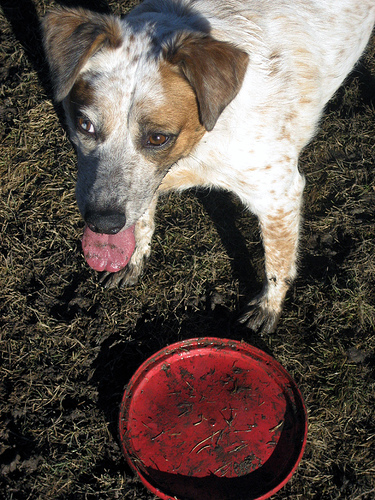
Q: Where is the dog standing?
A: In the mud.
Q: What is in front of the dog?
A: A frisbee.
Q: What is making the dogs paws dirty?
A: Mud.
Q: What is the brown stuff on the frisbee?
A: Mud.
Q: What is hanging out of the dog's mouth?
A: Tongue.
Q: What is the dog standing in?
A: Mud.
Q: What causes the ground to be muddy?
A: Water.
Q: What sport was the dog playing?
A: Frisbee.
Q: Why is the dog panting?
A: It is hot.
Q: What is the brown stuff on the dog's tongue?
A: Mud.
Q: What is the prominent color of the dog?
A: White.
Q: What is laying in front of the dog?
A: A Frisbee.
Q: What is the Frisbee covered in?
A: Dirt.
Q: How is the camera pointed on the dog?
A: Down.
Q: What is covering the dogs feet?
A: Mud.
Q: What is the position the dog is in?
A: Standing.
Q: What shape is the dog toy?
A: Round.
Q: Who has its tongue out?
A: The dog.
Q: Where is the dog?
A: On the ground.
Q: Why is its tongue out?
A: Thirsty.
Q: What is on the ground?
A: Bowl.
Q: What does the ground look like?
A: Muddy.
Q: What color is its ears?
A: Brown.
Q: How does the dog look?
A: Thirsty.